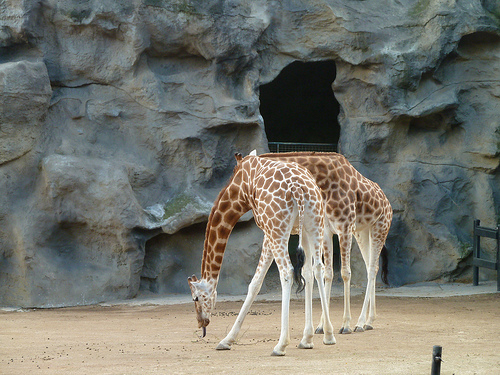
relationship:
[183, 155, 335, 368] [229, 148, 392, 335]
giraffe with giraffe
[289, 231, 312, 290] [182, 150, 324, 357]
tail on giraffe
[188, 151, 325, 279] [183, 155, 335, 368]
spots on giraffe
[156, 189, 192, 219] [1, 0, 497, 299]
green moss on cliffs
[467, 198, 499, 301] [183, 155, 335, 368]
fence to right of giraffe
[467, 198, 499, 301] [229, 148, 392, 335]
fence to right of giraffe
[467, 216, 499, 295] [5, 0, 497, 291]
fence on other side of cliffs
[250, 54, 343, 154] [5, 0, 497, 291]
big hole in cliffs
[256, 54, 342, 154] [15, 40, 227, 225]
big hole in rocks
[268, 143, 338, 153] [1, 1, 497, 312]
fence in rocks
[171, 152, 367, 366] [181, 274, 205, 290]
giraffe has ears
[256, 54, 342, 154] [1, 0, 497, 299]
big hole in cliffs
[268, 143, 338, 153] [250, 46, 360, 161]
fence inside hole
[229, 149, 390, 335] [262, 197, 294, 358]
giraffe have tall legs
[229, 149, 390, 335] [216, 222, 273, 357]
giraffe have tall legs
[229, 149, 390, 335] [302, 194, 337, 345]
giraffe have tall legs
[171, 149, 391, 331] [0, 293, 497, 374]
giraffe eating something from floor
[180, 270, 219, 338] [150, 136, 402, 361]
head of giraffe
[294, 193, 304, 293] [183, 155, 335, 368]
tail of giraffe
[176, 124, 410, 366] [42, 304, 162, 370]
two giraffes inside field